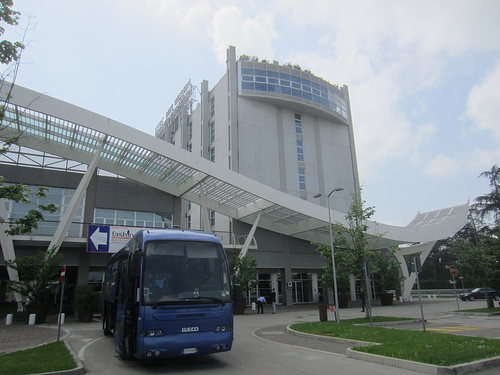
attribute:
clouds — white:
[395, 45, 488, 158]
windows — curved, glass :
[240, 66, 349, 122]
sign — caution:
[57, 264, 69, 283]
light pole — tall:
[313, 185, 346, 324]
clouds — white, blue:
[99, 2, 499, 227]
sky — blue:
[1, 2, 498, 226]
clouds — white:
[339, 4, 497, 194]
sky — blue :
[104, 0, 490, 189]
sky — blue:
[18, 12, 478, 212]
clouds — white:
[210, 12, 409, 150]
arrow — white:
[86, 217, 134, 256]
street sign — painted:
[432, 315, 487, 337]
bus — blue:
[98, 226, 238, 367]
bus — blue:
[108, 216, 285, 371]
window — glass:
[254, 72, 266, 79]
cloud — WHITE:
[2, 1, 492, 234]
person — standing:
[268, 287, 283, 315]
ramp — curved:
[2, 81, 485, 242]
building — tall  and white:
[6, 42, 378, 307]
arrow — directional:
[88, 224, 112, 249]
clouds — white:
[347, 23, 449, 160]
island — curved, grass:
[274, 300, 499, 366]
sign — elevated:
[81, 219, 219, 258]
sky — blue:
[394, 51, 474, 161]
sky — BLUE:
[423, 78, 472, 154]